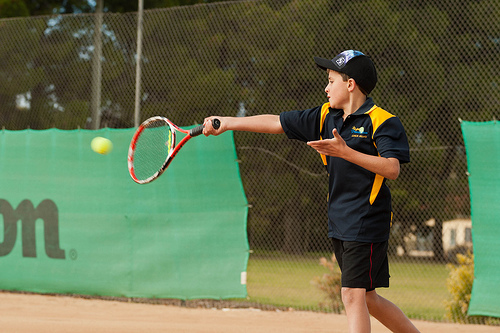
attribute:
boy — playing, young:
[194, 39, 425, 332]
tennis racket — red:
[121, 114, 201, 185]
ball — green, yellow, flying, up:
[88, 128, 118, 154]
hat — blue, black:
[315, 47, 385, 93]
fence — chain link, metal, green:
[8, 14, 499, 316]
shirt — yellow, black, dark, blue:
[276, 105, 422, 245]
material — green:
[4, 126, 500, 314]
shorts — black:
[319, 201, 397, 295]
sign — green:
[5, 131, 249, 303]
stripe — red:
[362, 243, 379, 290]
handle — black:
[194, 115, 222, 137]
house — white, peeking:
[409, 214, 482, 261]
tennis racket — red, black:
[123, 110, 207, 190]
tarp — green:
[8, 128, 499, 316]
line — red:
[356, 240, 382, 289]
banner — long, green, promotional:
[7, 121, 498, 319]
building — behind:
[383, 209, 478, 259]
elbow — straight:
[265, 111, 282, 136]